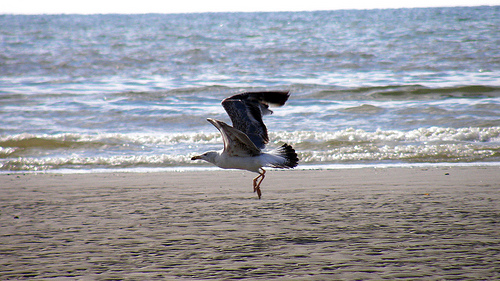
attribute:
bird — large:
[209, 94, 282, 255]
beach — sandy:
[1, 166, 498, 278]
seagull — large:
[188, 88, 299, 201]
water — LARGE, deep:
[85, 45, 195, 107]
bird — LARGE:
[188, 88, 296, 198]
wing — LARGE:
[220, 90, 292, 144]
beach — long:
[2, 227, 420, 269]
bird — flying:
[178, 99, 268, 161]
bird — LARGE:
[187, 85, 303, 202]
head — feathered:
[192, 146, 214, 170]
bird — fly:
[208, 89, 320, 191]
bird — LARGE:
[199, 94, 299, 193]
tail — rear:
[271, 138, 313, 190]